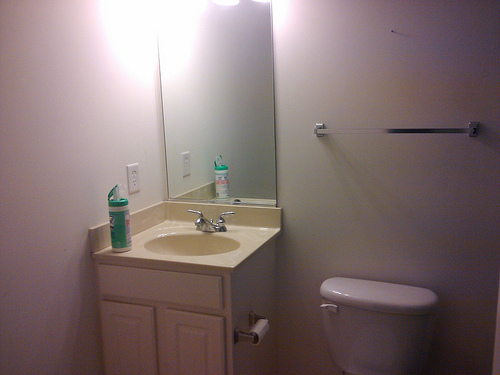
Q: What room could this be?
A: It is a bathroom.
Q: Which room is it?
A: It is a bathroom.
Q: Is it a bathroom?
A: Yes, it is a bathroom.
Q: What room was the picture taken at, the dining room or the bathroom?
A: It was taken at the bathroom.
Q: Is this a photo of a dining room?
A: No, the picture is showing a bathroom.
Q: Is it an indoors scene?
A: Yes, it is indoors.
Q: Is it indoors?
A: Yes, it is indoors.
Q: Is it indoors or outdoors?
A: It is indoors.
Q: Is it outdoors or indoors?
A: It is indoors.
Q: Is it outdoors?
A: No, it is indoors.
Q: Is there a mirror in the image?
A: Yes, there is a mirror.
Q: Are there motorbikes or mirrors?
A: Yes, there is a mirror.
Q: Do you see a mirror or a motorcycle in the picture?
A: Yes, there is a mirror.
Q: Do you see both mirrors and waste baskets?
A: No, there is a mirror but no waste baskets.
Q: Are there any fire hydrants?
A: No, there are no fire hydrants.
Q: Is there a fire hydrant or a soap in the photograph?
A: No, there are no fire hydrants or soaps.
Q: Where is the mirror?
A: The mirror is in the bathroom.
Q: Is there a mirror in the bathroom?
A: Yes, there is a mirror in the bathroom.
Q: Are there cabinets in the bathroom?
A: No, there is a mirror in the bathroom.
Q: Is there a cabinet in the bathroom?
A: No, there is a mirror in the bathroom.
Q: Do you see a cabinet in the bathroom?
A: No, there is a mirror in the bathroom.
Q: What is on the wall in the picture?
A: The mirror is on the wall.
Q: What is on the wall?
A: The mirror is on the wall.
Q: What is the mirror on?
A: The mirror is on the wall.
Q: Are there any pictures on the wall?
A: No, there is a mirror on the wall.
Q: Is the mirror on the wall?
A: Yes, the mirror is on the wall.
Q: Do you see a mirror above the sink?
A: Yes, there is a mirror above the sink.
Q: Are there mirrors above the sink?
A: Yes, there is a mirror above the sink.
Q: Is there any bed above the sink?
A: No, there is a mirror above the sink.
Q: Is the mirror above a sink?
A: Yes, the mirror is above a sink.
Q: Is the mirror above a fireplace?
A: No, the mirror is above a sink.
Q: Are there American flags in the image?
A: No, there are no American flags.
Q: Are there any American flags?
A: No, there are no American flags.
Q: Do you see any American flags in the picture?
A: No, there are no American flags.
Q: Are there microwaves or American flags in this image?
A: No, there are no American flags or microwaves.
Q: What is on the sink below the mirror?
A: The toilet roll is on the sink.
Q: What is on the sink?
A: The toilet roll is on the sink.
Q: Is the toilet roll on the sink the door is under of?
A: Yes, the toilet roll is on the sink.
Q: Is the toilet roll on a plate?
A: No, the toilet roll is on the sink.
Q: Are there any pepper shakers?
A: No, there are no pepper shakers.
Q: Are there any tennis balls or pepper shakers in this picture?
A: No, there are no pepper shakers or tennis balls.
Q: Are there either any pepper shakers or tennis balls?
A: No, there are no pepper shakers or tennis balls.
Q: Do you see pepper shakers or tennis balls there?
A: No, there are no pepper shakers or tennis balls.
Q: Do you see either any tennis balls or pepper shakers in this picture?
A: No, there are no pepper shakers or tennis balls.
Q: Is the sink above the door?
A: Yes, the sink is above the door.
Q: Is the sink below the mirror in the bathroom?
A: Yes, the sink is below the mirror.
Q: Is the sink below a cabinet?
A: No, the sink is below the mirror.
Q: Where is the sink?
A: The sink is in the bathroom.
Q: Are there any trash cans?
A: No, there are no trash cans.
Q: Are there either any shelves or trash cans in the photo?
A: No, there are no trash cans or shelves.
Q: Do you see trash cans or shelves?
A: No, there are no trash cans or shelves.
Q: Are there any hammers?
A: No, there are no hammers.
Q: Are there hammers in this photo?
A: No, there are no hammers.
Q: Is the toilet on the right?
A: Yes, the toilet is on the right of the image.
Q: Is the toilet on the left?
A: No, the toilet is on the right of the image.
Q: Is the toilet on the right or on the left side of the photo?
A: The toilet is on the right of the image.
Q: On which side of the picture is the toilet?
A: The toilet is on the right of the image.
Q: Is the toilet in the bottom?
A: Yes, the toilet is in the bottom of the image.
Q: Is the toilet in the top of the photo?
A: No, the toilet is in the bottom of the image.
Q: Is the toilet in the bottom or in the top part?
A: The toilet is in the bottom of the image.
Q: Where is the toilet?
A: The toilet is in the bathroom.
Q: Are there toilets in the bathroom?
A: Yes, there is a toilet in the bathroom.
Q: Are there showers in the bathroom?
A: No, there is a toilet in the bathroom.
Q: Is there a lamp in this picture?
A: No, there are no lamps.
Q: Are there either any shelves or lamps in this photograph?
A: No, there are no lamps or shelves.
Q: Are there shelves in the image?
A: No, there are no shelves.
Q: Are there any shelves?
A: No, there are no shelves.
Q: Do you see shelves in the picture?
A: No, there are no shelves.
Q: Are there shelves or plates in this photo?
A: No, there are no shelves or plates.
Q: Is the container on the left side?
A: Yes, the container is on the left of the image.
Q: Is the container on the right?
A: No, the container is on the left of the image.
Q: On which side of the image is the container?
A: The container is on the left of the image.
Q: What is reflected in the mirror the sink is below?
A: The container is reflected in the mirror.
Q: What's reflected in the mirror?
A: The container is reflected in the mirror.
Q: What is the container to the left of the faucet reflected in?
A: The container is reflected in the mirror.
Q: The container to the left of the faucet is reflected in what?
A: The container is reflected in the mirror.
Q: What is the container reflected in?
A: The container is reflected in the mirror.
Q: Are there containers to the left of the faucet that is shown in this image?
A: Yes, there is a container to the left of the faucet.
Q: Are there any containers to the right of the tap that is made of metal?
A: No, the container is to the left of the faucet.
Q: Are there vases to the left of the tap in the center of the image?
A: No, there is a container to the left of the faucet.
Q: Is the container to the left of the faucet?
A: Yes, the container is to the left of the faucet.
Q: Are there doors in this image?
A: Yes, there is a door.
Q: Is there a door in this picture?
A: Yes, there is a door.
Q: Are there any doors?
A: Yes, there is a door.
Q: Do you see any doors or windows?
A: Yes, there is a door.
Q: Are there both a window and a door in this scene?
A: No, there is a door but no windows.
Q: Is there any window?
A: No, there are no windows.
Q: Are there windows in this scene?
A: No, there are no windows.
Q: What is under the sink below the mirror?
A: The door is under the sink.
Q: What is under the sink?
A: The door is under the sink.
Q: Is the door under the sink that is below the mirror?
A: Yes, the door is under the sink.